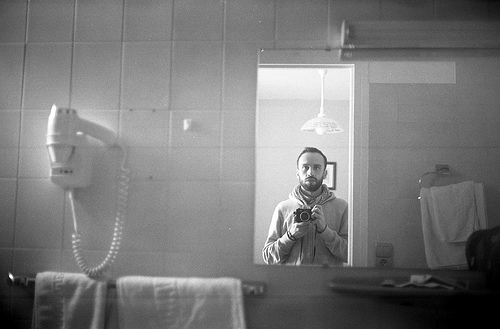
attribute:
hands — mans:
[283, 203, 328, 233]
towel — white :
[112, 270, 246, 326]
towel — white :
[31, 267, 108, 327]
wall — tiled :
[136, 0, 213, 254]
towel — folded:
[30, 274, 265, 328]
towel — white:
[115, 274, 245, 327]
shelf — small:
[327, 270, 467, 307]